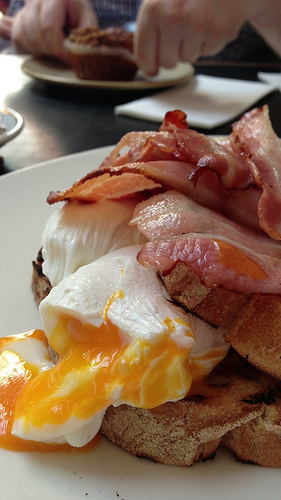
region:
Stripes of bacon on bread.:
[139, 127, 279, 230]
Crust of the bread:
[145, 406, 275, 481]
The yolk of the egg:
[57, 321, 172, 408]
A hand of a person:
[141, 1, 279, 73]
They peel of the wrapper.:
[16, 4, 236, 101]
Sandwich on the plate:
[18, 158, 120, 498]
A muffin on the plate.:
[65, 28, 143, 87]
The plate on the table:
[32, 68, 206, 97]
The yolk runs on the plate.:
[1, 325, 51, 455]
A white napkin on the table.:
[108, 83, 277, 132]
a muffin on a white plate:
[62, 22, 151, 85]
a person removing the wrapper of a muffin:
[14, 7, 230, 86]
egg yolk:
[30, 331, 117, 424]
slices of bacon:
[114, 116, 276, 237]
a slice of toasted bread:
[149, 371, 277, 486]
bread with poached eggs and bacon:
[32, 128, 277, 437]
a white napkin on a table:
[149, 71, 266, 117]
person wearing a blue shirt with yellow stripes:
[92, 0, 139, 24]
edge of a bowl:
[0, 91, 24, 152]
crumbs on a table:
[58, 462, 149, 498]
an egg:
[68, 232, 184, 485]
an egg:
[95, 241, 152, 487]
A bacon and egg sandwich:
[36, 122, 277, 469]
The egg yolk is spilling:
[7, 320, 177, 446]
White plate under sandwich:
[8, 157, 271, 489]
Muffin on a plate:
[33, 24, 185, 88]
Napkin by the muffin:
[135, 73, 263, 123]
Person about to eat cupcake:
[17, 1, 230, 76]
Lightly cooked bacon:
[141, 194, 274, 282]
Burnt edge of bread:
[228, 446, 259, 472]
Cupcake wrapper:
[67, 44, 139, 77]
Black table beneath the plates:
[30, 89, 102, 146]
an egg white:
[37, 242, 228, 362]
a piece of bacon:
[127, 192, 280, 294]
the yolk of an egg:
[1, 329, 186, 420]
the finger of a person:
[131, 8, 159, 76]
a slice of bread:
[100, 387, 279, 473]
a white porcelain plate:
[18, 52, 197, 93]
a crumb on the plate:
[110, 486, 125, 497]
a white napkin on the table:
[113, 66, 274, 134]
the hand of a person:
[131, 0, 248, 77]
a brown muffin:
[60, 20, 145, 80]